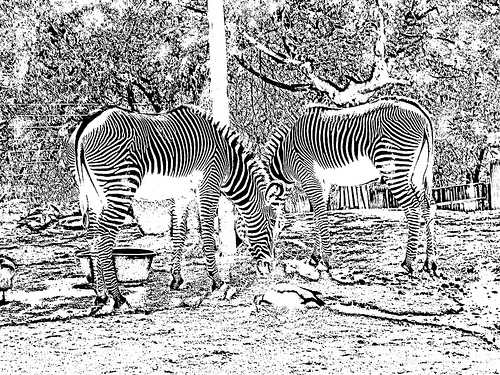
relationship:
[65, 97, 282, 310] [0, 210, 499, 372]
zebra grazing grass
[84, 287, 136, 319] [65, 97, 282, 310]
hooves on zebra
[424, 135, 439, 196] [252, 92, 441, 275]
tail on zebra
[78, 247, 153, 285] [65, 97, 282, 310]
bowl next to zebra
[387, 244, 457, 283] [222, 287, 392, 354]
zebra hooves on ground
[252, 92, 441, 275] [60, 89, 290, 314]
zebra by zebra